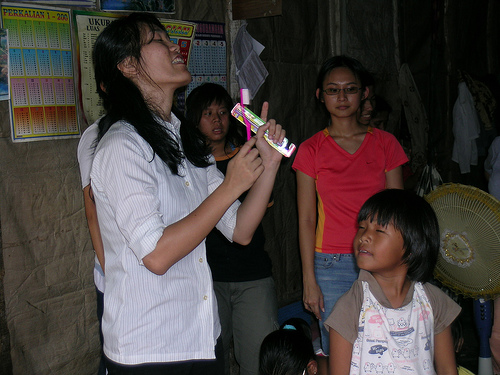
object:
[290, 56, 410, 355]
woman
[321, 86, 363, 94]
glasses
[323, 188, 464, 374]
child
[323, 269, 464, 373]
t-shirt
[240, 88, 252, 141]
toothbrush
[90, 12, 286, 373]
lady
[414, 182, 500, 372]
fan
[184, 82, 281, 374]
lady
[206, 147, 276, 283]
shirt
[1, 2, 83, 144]
calendar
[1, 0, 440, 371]
wall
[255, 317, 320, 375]
lady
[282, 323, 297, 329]
hair tie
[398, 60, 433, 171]
coat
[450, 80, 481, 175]
coat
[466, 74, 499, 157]
coat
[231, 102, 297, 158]
toothbrush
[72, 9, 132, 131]
sign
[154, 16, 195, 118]
sign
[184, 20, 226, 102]
sign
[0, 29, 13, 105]
sign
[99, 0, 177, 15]
sign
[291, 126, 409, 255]
shirt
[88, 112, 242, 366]
shirt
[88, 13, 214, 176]
hair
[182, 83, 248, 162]
hair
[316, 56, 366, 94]
hair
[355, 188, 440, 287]
hair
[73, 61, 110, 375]
woman